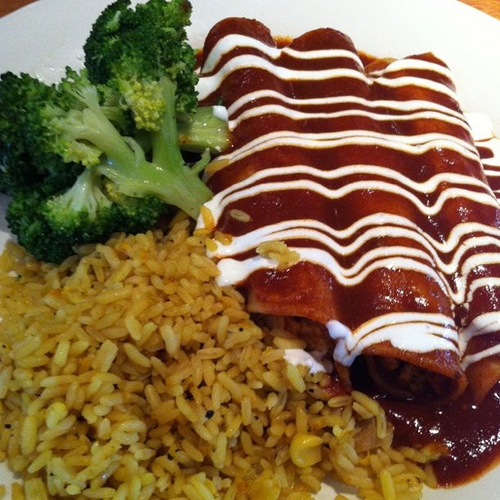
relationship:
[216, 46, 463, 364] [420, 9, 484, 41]
tamales under plate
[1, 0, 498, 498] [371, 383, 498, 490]
plate with red sauce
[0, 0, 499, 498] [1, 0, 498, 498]
food on plate